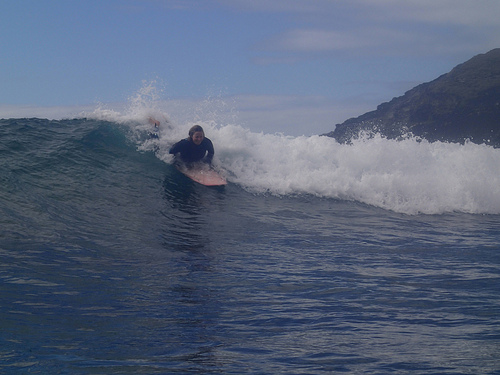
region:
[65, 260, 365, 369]
The water is blue.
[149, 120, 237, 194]
Surfer on a surfboard.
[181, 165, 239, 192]
The surfboard is pink.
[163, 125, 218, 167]
The wetsuit is black.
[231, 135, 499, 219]
The water is white.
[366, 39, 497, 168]
The water is dark grey.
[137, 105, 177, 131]
Feet in the water.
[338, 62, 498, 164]
The wave is rising.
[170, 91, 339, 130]
Clouds in the sky.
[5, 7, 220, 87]
The sky is blue.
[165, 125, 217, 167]
Woman in a black wet suit.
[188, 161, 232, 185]
A pink surf board.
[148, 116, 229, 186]
A woman on a surf board.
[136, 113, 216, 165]
A woman with wet hair.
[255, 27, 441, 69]
A white cloud in the sky.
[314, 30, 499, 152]
A hill next to the ocean.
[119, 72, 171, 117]
Splash from the wave.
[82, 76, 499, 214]
The crest of a wave.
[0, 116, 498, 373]
Dark blue ocean water.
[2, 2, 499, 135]
A blue sky with some white clouds.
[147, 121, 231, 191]
the woman on the surfboard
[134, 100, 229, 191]
the woman is surfing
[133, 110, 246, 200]
the woman in the ocean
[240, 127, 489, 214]
the wave is crashing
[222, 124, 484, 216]
the wave in the ocean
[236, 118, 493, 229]
the wave is foaming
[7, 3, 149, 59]
the clear blue sky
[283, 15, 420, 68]
the clouds in the sky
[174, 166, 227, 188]
the surfboard is pink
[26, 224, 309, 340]
the ocean is blue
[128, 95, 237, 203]
a person on the surfboard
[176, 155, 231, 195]
the surfboard is yellow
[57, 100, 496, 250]
the wave is white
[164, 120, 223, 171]
the person is wearing black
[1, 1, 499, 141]
the sky is cloudy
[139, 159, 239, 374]
a reflection in the water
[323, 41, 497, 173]
the wave is tall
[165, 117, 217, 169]
the person has hair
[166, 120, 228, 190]
the person's hands are on the surfboard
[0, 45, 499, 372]
the water is dark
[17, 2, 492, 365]
the surfer has caught a good wave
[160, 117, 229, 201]
the surfer is about to stand up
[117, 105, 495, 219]
the wave is about to break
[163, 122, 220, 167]
the person is wearing a wetsuit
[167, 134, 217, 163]
the full wetsuit is black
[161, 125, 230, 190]
the surfer is lying on the board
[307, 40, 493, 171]
a hill is behind the the wave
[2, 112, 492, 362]
the water is a deep blue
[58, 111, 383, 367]
the surfer is catching a nice size swell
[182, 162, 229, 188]
the surfboard is an orange color